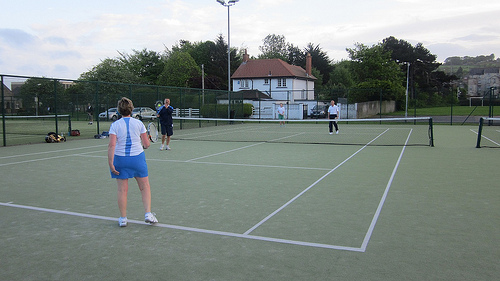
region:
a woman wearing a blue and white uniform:
[88, 92, 150, 241]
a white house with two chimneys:
[211, 48, 317, 120]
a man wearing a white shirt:
[317, 90, 344, 138]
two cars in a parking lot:
[92, 92, 154, 121]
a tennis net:
[163, 112, 435, 161]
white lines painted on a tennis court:
[213, 131, 411, 261]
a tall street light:
[382, 46, 427, 127]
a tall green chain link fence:
[0, 64, 123, 146]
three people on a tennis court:
[78, 80, 382, 250]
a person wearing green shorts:
[268, 92, 292, 130]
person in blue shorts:
[84, 97, 208, 255]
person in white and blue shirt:
[97, 81, 181, 178]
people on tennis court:
[78, 78, 229, 229]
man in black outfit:
[152, 88, 204, 156]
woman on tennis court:
[15, 105, 457, 275]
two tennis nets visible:
[138, 101, 495, 169]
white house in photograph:
[232, 44, 337, 141]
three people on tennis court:
[81, 82, 498, 233]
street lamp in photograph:
[187, 2, 279, 176]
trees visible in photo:
[37, 48, 495, 128]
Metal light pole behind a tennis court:
[214, 0, 242, 125]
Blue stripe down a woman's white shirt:
[115, 116, 135, 155]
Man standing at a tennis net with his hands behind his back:
[150, 99, 181, 155]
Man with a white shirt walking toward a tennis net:
[321, 98, 351, 137]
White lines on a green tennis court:
[196, 142, 417, 277]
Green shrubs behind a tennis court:
[197, 99, 261, 121]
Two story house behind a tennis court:
[226, 51, 321, 121]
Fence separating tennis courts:
[5, 71, 245, 136]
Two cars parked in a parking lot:
[92, 92, 163, 120]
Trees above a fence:
[72, 44, 264, 97]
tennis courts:
[10, 72, 498, 267]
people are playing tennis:
[89, 88, 451, 249]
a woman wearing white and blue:
[105, 94, 165, 228]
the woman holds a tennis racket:
[98, 92, 165, 230]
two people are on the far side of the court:
[263, 98, 341, 133]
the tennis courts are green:
[20, 78, 498, 259]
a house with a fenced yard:
[220, 50, 402, 114]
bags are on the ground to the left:
[45, 122, 126, 141]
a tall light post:
[215, 0, 240, 117]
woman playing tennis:
[75, 82, 170, 252]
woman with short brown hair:
[92, 76, 174, 235]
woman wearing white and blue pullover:
[68, 91, 155, 229]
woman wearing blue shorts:
[80, 54, 230, 231]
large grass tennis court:
[3, 100, 433, 228]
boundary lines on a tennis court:
[9, 106, 467, 252]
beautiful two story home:
[186, 43, 341, 139]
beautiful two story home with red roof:
[175, 43, 332, 131]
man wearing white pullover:
[298, 89, 362, 176]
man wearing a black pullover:
[142, 75, 205, 162]